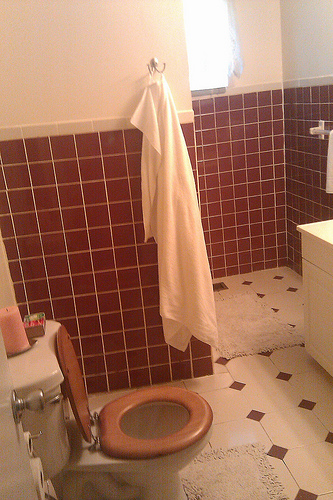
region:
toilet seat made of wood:
[99, 387, 213, 457]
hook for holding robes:
[138, 54, 170, 75]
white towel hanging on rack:
[129, 70, 213, 348]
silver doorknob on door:
[16, 386, 43, 410]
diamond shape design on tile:
[227, 377, 255, 390]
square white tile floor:
[242, 379, 294, 405]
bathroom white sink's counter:
[297, 218, 328, 352]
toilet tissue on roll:
[30, 453, 54, 492]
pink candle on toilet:
[0, 303, 29, 354]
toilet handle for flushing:
[47, 390, 65, 417]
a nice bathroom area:
[3, 264, 283, 499]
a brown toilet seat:
[49, 317, 230, 479]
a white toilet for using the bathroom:
[11, 313, 218, 499]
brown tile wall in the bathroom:
[27, 211, 212, 379]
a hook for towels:
[129, 55, 180, 93]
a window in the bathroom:
[176, 2, 237, 102]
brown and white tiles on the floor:
[226, 366, 325, 451]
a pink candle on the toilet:
[0, 305, 29, 354]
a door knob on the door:
[4, 377, 48, 418]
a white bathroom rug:
[191, 435, 289, 495]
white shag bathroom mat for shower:
[212, 288, 302, 361]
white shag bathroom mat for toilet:
[178, 440, 289, 497]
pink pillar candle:
[0, 304, 30, 355]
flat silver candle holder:
[5, 338, 36, 358]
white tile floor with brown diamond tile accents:
[43, 264, 332, 499]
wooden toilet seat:
[99, 384, 212, 460]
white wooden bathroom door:
[0, 328, 38, 498]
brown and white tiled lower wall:
[0, 74, 332, 395]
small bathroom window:
[180, 0, 228, 91]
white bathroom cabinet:
[295, 219, 332, 376]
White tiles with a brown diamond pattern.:
[66, 263, 331, 498]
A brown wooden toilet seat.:
[54, 321, 215, 457]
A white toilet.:
[2, 316, 213, 499]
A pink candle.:
[1, 304, 32, 351]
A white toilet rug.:
[184, 444, 291, 499]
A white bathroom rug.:
[206, 287, 303, 362]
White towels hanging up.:
[136, 69, 225, 355]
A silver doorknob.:
[8, 388, 47, 423]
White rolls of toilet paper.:
[22, 430, 58, 498]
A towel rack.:
[307, 119, 332, 139]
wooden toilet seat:
[52, 321, 215, 458]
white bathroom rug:
[179, 439, 293, 499]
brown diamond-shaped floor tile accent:
[244, 407, 268, 422]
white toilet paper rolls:
[18, 428, 57, 499]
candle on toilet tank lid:
[0, 301, 32, 357]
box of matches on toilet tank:
[22, 310, 47, 337]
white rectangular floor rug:
[201, 292, 301, 360]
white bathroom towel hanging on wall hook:
[130, 57, 220, 353]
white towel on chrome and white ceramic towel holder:
[307, 117, 332, 193]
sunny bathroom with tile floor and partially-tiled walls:
[8, 4, 327, 492]